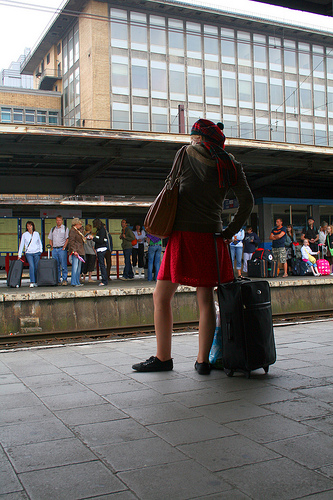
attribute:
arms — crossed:
[267, 231, 285, 242]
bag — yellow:
[306, 254, 316, 264]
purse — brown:
[143, 144, 185, 238]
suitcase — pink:
[314, 241, 331, 278]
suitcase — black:
[209, 229, 281, 381]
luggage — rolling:
[5, 257, 20, 289]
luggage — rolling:
[36, 255, 58, 286]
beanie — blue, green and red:
[189, 118, 225, 147]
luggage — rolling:
[212, 272, 281, 378]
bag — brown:
[142, 176, 180, 239]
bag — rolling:
[212, 236, 277, 377]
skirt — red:
[156, 229, 234, 287]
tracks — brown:
[3, 302, 302, 357]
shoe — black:
[132, 355, 174, 370]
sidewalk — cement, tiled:
[1, 321, 323, 497]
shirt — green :
[143, 227, 166, 249]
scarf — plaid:
[196, 136, 240, 195]